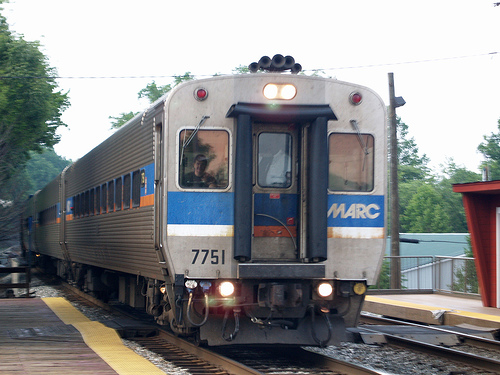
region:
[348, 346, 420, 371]
a pile of gravel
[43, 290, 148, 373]
a thick yellow stripe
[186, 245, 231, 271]
a number displayed on a train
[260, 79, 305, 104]
a pair of lights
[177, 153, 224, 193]
a man driving a train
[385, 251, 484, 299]
a low metal fence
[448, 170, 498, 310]
a red wood structure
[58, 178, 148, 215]
a row of windows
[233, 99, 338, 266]
a metal door framed in black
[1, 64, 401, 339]
a train with a blue stripe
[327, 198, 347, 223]
The letter is white.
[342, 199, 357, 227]
The letter is white.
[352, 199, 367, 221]
The letter is white.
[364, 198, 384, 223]
The letter is white.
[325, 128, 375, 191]
The window is rectangular.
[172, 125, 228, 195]
The window is rectangular.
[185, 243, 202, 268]
The number is black.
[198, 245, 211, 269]
The number is black.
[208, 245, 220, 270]
The number is black.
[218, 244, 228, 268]
The number is black.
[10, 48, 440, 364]
train on the tracks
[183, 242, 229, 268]
black numbers on the train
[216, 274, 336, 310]
two lights on the train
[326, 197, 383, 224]
white writing on a blue background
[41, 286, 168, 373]
thick yellow line on the ground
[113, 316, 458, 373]
gravel on the tracks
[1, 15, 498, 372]
train pulling into a staion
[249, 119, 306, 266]
door on the train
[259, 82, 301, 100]
light on the top of the train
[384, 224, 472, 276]
roof of a building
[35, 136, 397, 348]
grey and blue train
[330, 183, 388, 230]
white name on train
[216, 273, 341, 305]
white lights on train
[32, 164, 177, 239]
blue and orange stripe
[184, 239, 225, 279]
black numbers on train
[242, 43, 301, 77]
black horn on top of train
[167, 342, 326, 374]
brown tracks under train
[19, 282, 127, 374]
yellow line on platform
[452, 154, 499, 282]
red building next to train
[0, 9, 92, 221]
green tree beside train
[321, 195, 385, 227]
a company name on a train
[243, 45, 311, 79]
train whistles on top of a traim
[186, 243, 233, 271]
an identification number on a train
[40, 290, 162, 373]
a yellow warning strip on a train platform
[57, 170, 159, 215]
windows on a passenger train car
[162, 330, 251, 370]
a train track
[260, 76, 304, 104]
lighting on a train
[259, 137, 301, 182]
a man visible through a train window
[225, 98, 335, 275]
the back door of a train car